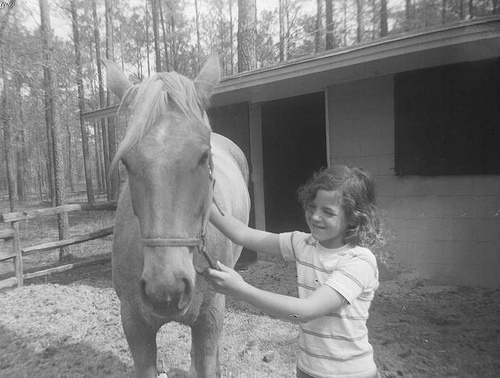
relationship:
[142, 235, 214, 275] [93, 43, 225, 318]
halter on head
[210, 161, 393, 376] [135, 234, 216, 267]
child looking at halter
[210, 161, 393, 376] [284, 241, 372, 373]
child wearing shirt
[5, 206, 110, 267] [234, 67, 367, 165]
wooden fence beside stall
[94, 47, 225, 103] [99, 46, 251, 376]
ears of horse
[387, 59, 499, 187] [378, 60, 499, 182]
board over window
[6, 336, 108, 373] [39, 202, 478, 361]
shadow on ground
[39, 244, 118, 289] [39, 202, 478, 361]
shadow on ground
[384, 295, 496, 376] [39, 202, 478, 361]
shadow on ground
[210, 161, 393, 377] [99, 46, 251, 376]
child on a horse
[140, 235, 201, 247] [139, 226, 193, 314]
strap across horses mouth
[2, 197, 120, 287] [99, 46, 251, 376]
fence for a horse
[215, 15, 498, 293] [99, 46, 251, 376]
building that houses a horse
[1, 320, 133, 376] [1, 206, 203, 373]
shadow on ground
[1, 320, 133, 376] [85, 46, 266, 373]
shadow from horse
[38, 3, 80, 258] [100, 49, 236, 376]
trees behind horse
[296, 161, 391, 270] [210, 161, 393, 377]
hair on child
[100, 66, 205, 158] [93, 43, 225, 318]
hair on a horses head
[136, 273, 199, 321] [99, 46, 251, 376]
horse's nose of a horse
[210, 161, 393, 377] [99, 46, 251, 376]
child touching a horse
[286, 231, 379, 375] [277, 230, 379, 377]
stripes on front of shirt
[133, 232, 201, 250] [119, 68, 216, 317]
rope around horses face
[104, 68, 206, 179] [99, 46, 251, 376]
mane of a horse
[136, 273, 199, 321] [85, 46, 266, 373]
horse's nose on a horse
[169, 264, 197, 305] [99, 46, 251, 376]
nostril on a horse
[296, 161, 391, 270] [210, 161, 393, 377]
hair on a child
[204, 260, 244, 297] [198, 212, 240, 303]
hand grabbing a rope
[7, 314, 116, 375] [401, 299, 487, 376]
imprints in dirt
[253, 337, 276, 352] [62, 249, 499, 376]
imprint in dirt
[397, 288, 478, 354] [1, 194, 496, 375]
small imprints in dirt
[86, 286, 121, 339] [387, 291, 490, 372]
imprints in dirt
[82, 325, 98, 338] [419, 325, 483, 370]
imprint in dirt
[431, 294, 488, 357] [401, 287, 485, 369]
imprints in dirt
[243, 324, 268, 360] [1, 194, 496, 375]
imprints in dirt